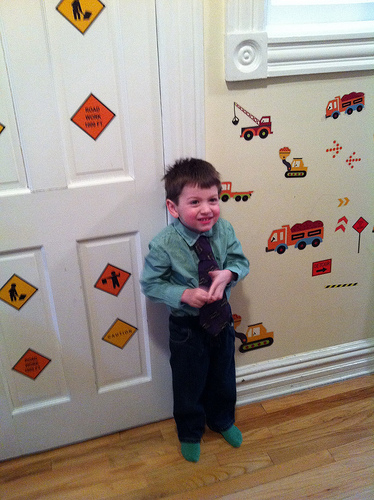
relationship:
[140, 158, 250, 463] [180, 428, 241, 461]
kid wearing socks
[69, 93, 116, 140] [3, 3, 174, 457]
sticker on door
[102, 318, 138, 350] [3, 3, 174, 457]
sticker on door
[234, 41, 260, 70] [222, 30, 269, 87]
design on corner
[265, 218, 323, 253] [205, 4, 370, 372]
sticker on wall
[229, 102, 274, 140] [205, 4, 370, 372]
sticker on wall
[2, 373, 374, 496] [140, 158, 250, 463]
floor under kid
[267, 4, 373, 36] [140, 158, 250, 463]
window above kid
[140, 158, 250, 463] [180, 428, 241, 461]
kid wears socks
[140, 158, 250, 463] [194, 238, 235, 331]
kid wears tie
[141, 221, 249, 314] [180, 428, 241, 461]
shirt matches socks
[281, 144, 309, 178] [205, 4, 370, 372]
sticker on wall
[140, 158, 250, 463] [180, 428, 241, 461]
kid has socks